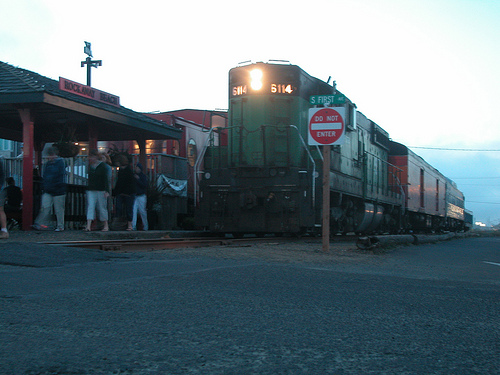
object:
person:
[2, 177, 23, 232]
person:
[110, 154, 136, 232]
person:
[0, 162, 10, 240]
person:
[16, 142, 24, 158]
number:
[232, 85, 248, 96]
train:
[197, 57, 474, 240]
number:
[270, 83, 294, 94]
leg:
[138, 195, 149, 231]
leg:
[131, 198, 138, 232]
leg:
[125, 192, 135, 232]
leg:
[115, 193, 123, 218]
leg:
[80, 191, 96, 232]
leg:
[97, 191, 111, 232]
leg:
[52, 193, 66, 234]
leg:
[30, 191, 54, 232]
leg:
[0, 191, 10, 240]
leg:
[4, 205, 15, 230]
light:
[248, 67, 264, 80]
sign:
[307, 106, 346, 146]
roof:
[0, 61, 184, 142]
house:
[0, 59, 184, 231]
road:
[1, 235, 498, 375]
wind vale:
[80, 40, 104, 87]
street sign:
[306, 93, 346, 255]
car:
[191, 57, 407, 239]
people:
[29, 145, 69, 232]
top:
[224, 57, 392, 148]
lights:
[249, 79, 265, 92]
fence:
[0, 157, 187, 230]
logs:
[353, 234, 416, 250]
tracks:
[55, 237, 294, 253]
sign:
[308, 94, 345, 106]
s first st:
[310, 95, 345, 105]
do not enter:
[313, 114, 339, 139]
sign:
[57, 75, 120, 108]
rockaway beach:
[63, 80, 120, 106]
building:
[131, 107, 228, 205]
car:
[387, 138, 449, 233]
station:
[0, 61, 182, 237]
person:
[81, 153, 112, 232]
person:
[132, 163, 150, 230]